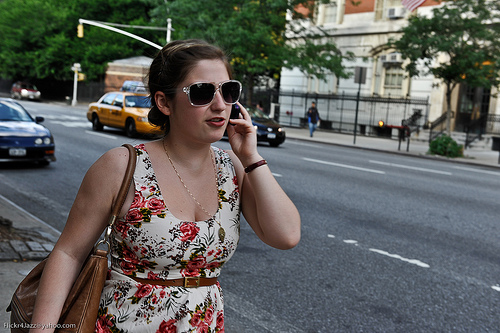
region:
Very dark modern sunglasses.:
[150, 78, 245, 108]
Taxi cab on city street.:
[85, 89, 169, 140]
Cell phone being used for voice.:
[225, 99, 242, 127]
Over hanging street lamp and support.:
[74, 13, 174, 57]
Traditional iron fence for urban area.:
[2, 69, 434, 147]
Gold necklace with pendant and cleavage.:
[159, 132, 230, 247]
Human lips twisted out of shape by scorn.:
[199, 115, 228, 127]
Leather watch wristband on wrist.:
[240, 157, 270, 174]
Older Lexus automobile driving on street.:
[0, 96, 59, 172]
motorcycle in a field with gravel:
[261, 265, 268, 267]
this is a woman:
[48, 51, 378, 258]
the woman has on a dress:
[119, 153, 292, 288]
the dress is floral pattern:
[104, 172, 296, 307]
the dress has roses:
[131, 188, 276, 329]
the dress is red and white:
[119, 184, 261, 320]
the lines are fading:
[343, 209, 444, 267]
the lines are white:
[330, 218, 452, 307]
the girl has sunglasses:
[112, 27, 273, 140]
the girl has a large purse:
[104, 132, 161, 287]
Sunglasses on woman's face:
[187, 80, 242, 102]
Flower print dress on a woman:
[101, 143, 233, 332]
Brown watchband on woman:
[238, 155, 268, 170]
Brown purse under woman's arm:
[8, 253, 110, 330]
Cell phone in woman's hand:
[231, 103, 238, 120]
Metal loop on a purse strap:
[96, 240, 111, 252]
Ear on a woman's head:
[150, 91, 172, 119]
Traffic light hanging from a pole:
[77, 25, 86, 39]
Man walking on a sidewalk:
[304, 100, 321, 138]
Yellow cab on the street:
[86, 80, 156, 137]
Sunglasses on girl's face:
[185, 78, 242, 109]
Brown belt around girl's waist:
[133, 271, 231, 288]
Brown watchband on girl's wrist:
[244, 155, 268, 170]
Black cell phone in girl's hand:
[232, 101, 244, 117]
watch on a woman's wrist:
[241, 154, 268, 177]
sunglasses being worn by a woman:
[155, 77, 247, 113]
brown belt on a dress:
[107, 265, 220, 291]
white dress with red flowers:
[95, 139, 245, 331]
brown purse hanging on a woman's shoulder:
[5, 138, 147, 330]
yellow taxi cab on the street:
[85, 77, 160, 140]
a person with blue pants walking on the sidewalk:
[302, 100, 322, 143]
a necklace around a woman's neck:
[157, 135, 224, 222]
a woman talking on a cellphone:
[6, 36, 313, 331]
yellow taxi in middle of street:
[85, 90, 161, 136]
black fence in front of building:
[242, 85, 430, 137]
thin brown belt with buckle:
[124, 274, 218, 287]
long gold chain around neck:
[159, 137, 221, 217]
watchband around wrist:
[243, 157, 266, 172]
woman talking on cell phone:
[7, 39, 302, 331]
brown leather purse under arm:
[5, 143, 136, 331]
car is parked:
[2, 96, 59, 170]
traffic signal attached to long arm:
[76, 17, 173, 51]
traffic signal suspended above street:
[77, 23, 83, 38]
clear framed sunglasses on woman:
[155, 78, 245, 111]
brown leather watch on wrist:
[238, 153, 271, 175]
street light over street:
[71, 12, 175, 61]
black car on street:
[0, 93, 60, 173]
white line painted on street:
[319, 226, 433, 281]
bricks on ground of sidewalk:
[1, 225, 58, 265]